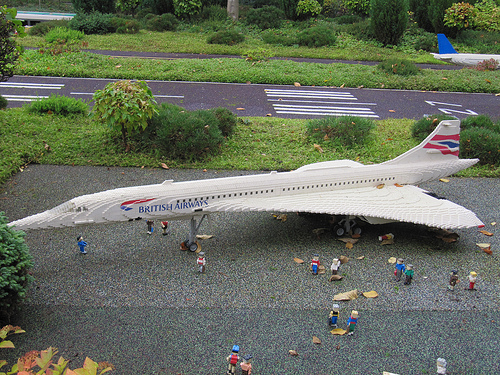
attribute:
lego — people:
[305, 283, 383, 345]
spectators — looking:
[384, 253, 417, 285]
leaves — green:
[85, 76, 152, 122]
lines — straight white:
[272, 106, 350, 113]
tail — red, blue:
[420, 130, 468, 166]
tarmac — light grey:
[35, 164, 500, 370]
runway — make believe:
[11, 76, 488, 126]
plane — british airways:
[7, 114, 492, 275]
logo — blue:
[138, 199, 208, 213]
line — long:
[66, 83, 181, 102]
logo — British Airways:
[425, 120, 467, 170]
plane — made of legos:
[3, 113, 489, 246]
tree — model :
[109, 95, 143, 149]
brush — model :
[153, 100, 184, 135]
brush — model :
[181, 109, 219, 150]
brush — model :
[213, 107, 247, 134]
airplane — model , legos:
[3, 126, 493, 231]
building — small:
[6, 7, 78, 28]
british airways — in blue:
[135, 199, 213, 215]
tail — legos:
[428, 27, 494, 74]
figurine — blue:
[64, 231, 97, 262]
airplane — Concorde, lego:
[3, 111, 487, 254]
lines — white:
[232, 57, 477, 129]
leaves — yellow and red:
[2, 316, 126, 374]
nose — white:
[1, 203, 56, 265]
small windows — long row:
[176, 173, 398, 207]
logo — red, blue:
[125, 199, 211, 221]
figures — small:
[249, 244, 484, 341]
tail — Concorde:
[402, 106, 483, 184]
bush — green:
[90, 79, 155, 149]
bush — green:
[148, 94, 182, 135]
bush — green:
[157, 106, 223, 162]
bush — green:
[208, 105, 238, 133]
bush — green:
[25, 91, 88, 113]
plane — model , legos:
[422, 25, 498, 75]